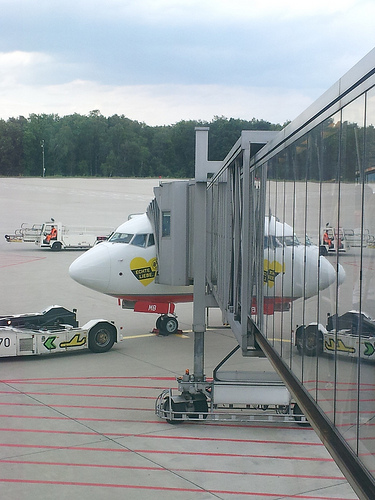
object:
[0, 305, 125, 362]
car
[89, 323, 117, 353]
wheel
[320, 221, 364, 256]
car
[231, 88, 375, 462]
line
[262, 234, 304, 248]
windows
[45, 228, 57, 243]
orange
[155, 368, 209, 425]
front wheels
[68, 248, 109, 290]
nose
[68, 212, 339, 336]
airplane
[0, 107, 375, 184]
green trees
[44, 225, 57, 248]
man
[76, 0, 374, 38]
white cloud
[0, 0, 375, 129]
blue sky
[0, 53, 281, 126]
clouds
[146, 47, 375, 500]
bridge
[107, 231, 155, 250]
windows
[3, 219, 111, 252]
truck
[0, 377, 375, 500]
line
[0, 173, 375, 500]
ground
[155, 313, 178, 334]
wheel